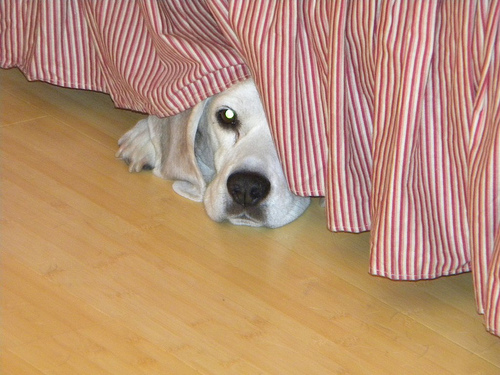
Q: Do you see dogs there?
A: Yes, there is a dog.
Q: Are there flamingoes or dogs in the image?
A: Yes, there is a dog.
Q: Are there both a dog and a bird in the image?
A: No, there is a dog but no birds.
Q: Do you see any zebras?
A: No, there are no zebras.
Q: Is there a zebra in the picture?
A: No, there are no zebras.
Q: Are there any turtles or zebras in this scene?
A: No, there are no zebras or turtles.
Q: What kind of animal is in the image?
A: The animal is a dog.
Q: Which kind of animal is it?
A: The animal is a dog.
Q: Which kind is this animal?
A: This is a dog.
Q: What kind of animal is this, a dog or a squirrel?
A: This is a dog.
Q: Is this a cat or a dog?
A: This is a dog.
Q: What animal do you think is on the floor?
A: The dog is on the floor.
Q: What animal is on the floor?
A: The dog is on the floor.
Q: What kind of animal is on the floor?
A: The animal is a dog.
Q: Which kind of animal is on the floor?
A: The animal is a dog.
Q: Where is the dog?
A: The dog is on the floor.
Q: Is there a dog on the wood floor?
A: Yes, there is a dog on the floor.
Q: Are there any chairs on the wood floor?
A: No, there is a dog on the floor.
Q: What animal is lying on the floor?
A: The dog is lying on the floor.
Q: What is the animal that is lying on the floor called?
A: The animal is a dog.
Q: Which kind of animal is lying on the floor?
A: The animal is a dog.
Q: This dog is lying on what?
A: The dog is lying on the floor.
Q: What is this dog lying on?
A: The dog is lying on the floor.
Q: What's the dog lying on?
A: The dog is lying on the floor.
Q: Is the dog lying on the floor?
A: Yes, the dog is lying on the floor.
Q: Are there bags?
A: No, there are no bags.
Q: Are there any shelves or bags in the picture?
A: No, there are no bags or shelves.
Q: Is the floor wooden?
A: Yes, the floor is wooden.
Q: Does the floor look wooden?
A: Yes, the floor is wooden.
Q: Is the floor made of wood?
A: Yes, the floor is made of wood.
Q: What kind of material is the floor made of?
A: The floor is made of wood.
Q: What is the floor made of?
A: The floor is made of wood.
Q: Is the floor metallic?
A: No, the floor is wooden.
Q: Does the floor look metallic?
A: No, the floor is wooden.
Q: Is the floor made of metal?
A: No, the floor is made of wood.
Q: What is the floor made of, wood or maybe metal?
A: The floor is made of wood.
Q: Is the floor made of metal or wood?
A: The floor is made of wood.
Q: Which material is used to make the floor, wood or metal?
A: The floor is made of wood.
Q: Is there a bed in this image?
A: Yes, there is a bed.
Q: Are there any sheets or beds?
A: Yes, there is a bed.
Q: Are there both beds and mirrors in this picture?
A: No, there is a bed but no mirrors.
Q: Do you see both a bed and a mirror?
A: No, there is a bed but no mirrors.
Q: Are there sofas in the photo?
A: No, there are no sofas.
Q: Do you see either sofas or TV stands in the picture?
A: No, there are no sofas or TV stands.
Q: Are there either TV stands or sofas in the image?
A: No, there are no sofas or TV stands.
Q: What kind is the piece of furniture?
A: The piece of furniture is a bed.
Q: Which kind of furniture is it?
A: The piece of furniture is a bed.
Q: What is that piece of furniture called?
A: This is a bed.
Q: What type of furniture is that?
A: This is a bed.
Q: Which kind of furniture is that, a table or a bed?
A: This is a bed.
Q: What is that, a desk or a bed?
A: That is a bed.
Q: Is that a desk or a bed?
A: That is a bed.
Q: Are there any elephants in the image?
A: No, there are no elephants.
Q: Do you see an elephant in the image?
A: No, there are no elephants.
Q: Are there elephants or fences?
A: No, there are no elephants or fences.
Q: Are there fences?
A: No, there are no fences.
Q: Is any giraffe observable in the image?
A: No, there are no giraffes.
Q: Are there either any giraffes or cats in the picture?
A: No, there are no giraffes or cats.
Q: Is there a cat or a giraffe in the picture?
A: No, there are no giraffes or cats.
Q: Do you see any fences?
A: No, there are no fences.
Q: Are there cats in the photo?
A: No, there are no cats.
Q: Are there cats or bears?
A: No, there are no cats or bears.